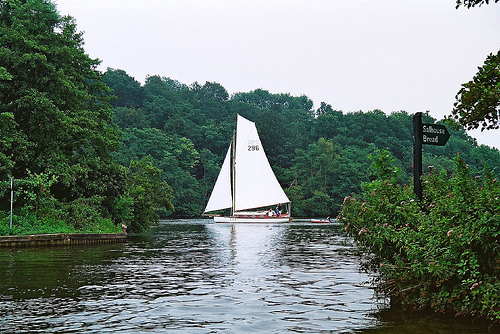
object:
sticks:
[10, 176, 14, 229]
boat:
[200, 113, 292, 223]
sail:
[235, 110, 291, 212]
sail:
[203, 140, 234, 217]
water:
[0, 218, 500, 334]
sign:
[421, 123, 451, 146]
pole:
[413, 112, 424, 200]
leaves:
[0, 0, 119, 187]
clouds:
[49, 0, 500, 151]